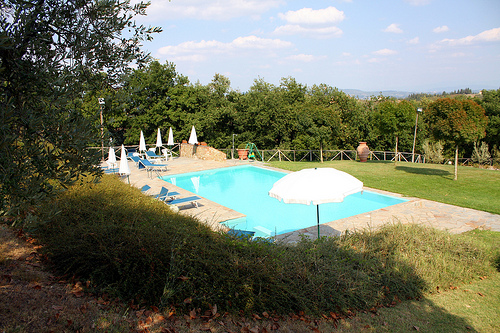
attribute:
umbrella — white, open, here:
[275, 164, 360, 209]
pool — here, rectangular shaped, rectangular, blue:
[159, 159, 397, 237]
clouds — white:
[124, 8, 481, 83]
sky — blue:
[2, 2, 499, 104]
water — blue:
[177, 167, 397, 243]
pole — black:
[314, 206, 324, 243]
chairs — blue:
[127, 151, 248, 238]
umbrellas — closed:
[138, 126, 198, 170]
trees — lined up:
[72, 52, 500, 158]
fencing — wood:
[88, 143, 499, 172]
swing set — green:
[243, 140, 265, 164]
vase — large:
[356, 141, 371, 161]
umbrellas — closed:
[104, 137, 131, 180]